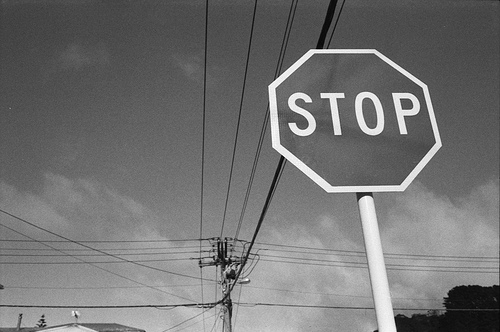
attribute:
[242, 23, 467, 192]
sign — black, red, octagon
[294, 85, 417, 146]
lettering — white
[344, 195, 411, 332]
pole — metal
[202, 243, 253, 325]
pole — tall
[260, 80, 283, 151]
border — white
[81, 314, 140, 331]
roof — arched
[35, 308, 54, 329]
tree — tall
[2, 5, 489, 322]
photo — black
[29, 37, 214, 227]
sky — cloudy, hazy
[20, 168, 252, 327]
clouds — white, wispy